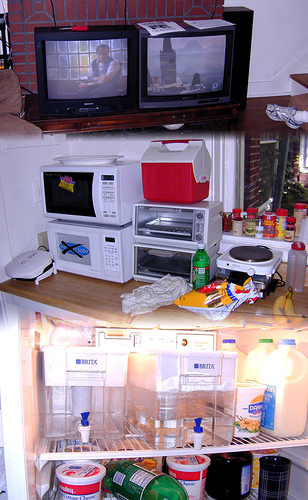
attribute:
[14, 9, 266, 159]
tvs — are small, are adjacent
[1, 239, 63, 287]
grill — white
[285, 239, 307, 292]
plastic bottle — clear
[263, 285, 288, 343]
banana — yellow 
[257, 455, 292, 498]
mug — black, coffee, white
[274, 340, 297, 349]
lid — blue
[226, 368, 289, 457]
container — white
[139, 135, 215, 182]
lid — white